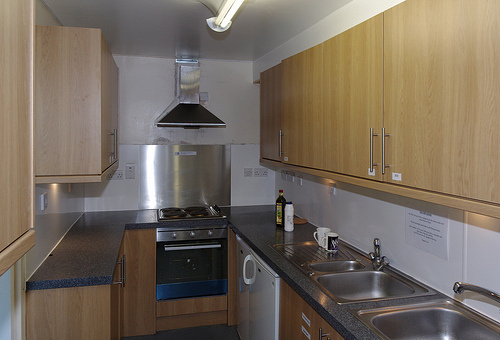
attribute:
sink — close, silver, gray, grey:
[321, 264, 492, 339]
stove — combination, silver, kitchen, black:
[156, 200, 232, 297]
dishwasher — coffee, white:
[232, 239, 280, 339]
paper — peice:
[400, 206, 452, 261]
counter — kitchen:
[24, 205, 162, 293]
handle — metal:
[366, 124, 388, 175]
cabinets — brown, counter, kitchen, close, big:
[255, 4, 498, 222]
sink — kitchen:
[313, 263, 431, 305]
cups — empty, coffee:
[310, 224, 339, 251]